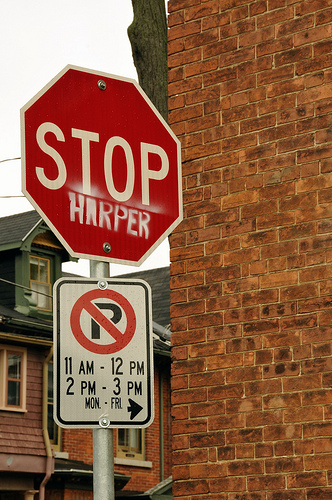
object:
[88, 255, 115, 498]
pipe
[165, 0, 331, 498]
brick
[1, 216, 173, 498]
building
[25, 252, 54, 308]
window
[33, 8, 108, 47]
sky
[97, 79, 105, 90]
screw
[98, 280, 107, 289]
screw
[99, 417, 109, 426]
screw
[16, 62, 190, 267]
stop sign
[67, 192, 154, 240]
graffiti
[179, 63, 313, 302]
red brick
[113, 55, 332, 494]
building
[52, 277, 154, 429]
sign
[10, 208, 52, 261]
house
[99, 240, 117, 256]
bolts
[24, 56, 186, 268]
sign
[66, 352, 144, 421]
hours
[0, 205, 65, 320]
attic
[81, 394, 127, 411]
lettering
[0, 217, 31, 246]
shingles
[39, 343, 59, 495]
drain pipe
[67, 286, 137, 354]
letter p